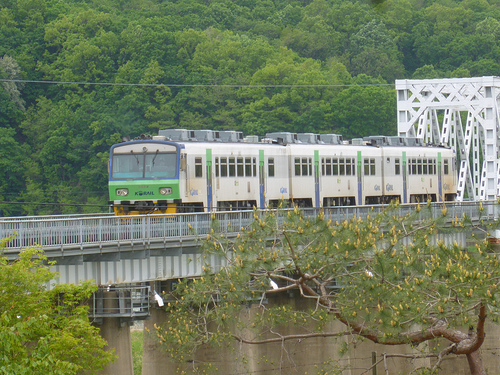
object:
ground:
[396, 172, 419, 205]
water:
[0, 259, 498, 373]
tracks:
[1, 200, 498, 292]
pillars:
[393, 76, 499, 203]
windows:
[227, 155, 237, 175]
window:
[443, 158, 449, 175]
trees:
[0, 1, 43, 69]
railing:
[0, 193, 498, 256]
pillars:
[102, 290, 121, 317]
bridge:
[384, 76, 499, 202]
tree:
[144, 197, 495, 374]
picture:
[0, 0, 499, 375]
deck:
[84, 281, 153, 327]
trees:
[25, 85, 98, 147]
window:
[394, 158, 401, 175]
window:
[214, 156, 219, 178]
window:
[268, 157, 275, 178]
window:
[395, 159, 400, 174]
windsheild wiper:
[151, 149, 157, 165]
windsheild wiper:
[129, 150, 141, 165]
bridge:
[0, 200, 500, 301]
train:
[108, 130, 459, 224]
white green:
[106, 126, 458, 216]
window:
[195, 156, 204, 176]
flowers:
[367, 242, 383, 252]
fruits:
[403, 276, 413, 284]